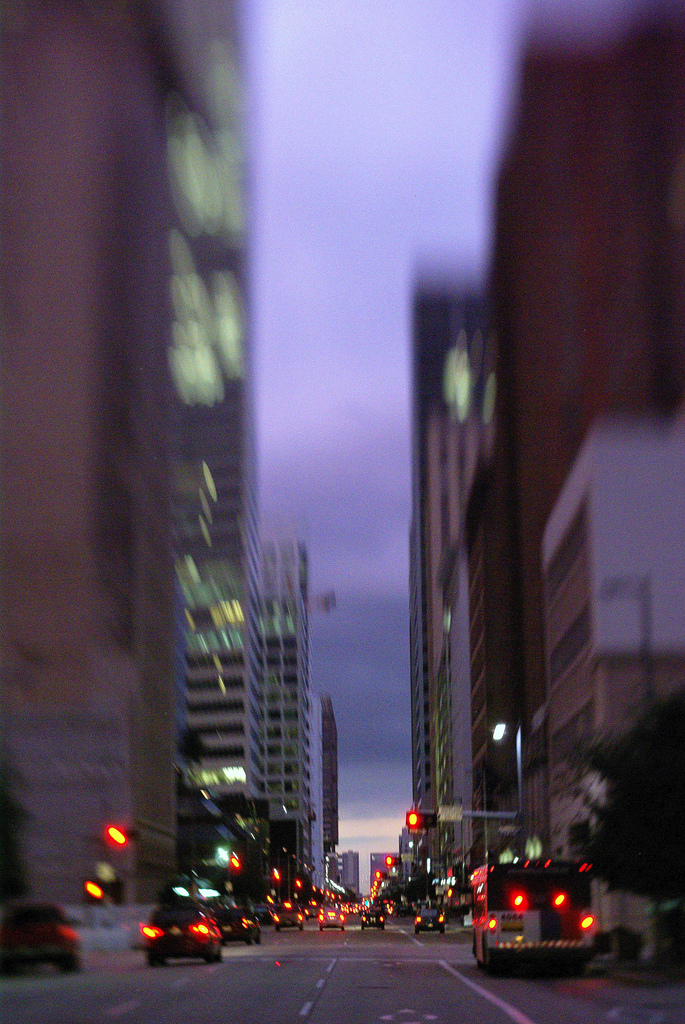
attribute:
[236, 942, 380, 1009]
lines — white